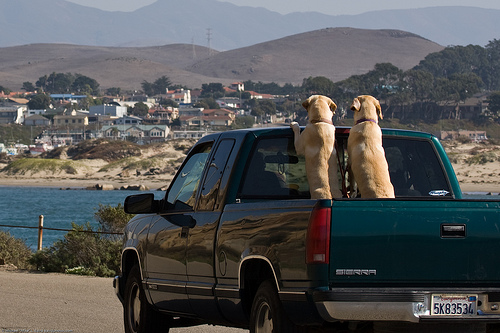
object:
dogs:
[290, 94, 338, 206]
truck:
[113, 94, 499, 332]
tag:
[429, 292, 478, 316]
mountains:
[0, 26, 445, 92]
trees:
[405, 37, 499, 123]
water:
[0, 186, 129, 236]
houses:
[20, 113, 55, 125]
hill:
[0, 55, 270, 92]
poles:
[205, 27, 214, 56]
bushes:
[0, 201, 137, 277]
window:
[164, 142, 215, 212]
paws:
[289, 121, 301, 128]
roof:
[200, 125, 439, 140]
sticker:
[427, 188, 451, 197]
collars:
[307, 117, 334, 123]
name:
[336, 267, 378, 275]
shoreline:
[0, 172, 175, 191]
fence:
[0, 209, 135, 272]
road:
[0, 270, 125, 332]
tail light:
[305, 206, 330, 264]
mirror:
[122, 193, 155, 215]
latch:
[440, 224, 467, 238]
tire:
[247, 277, 294, 332]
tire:
[123, 263, 170, 332]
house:
[97, 122, 172, 145]